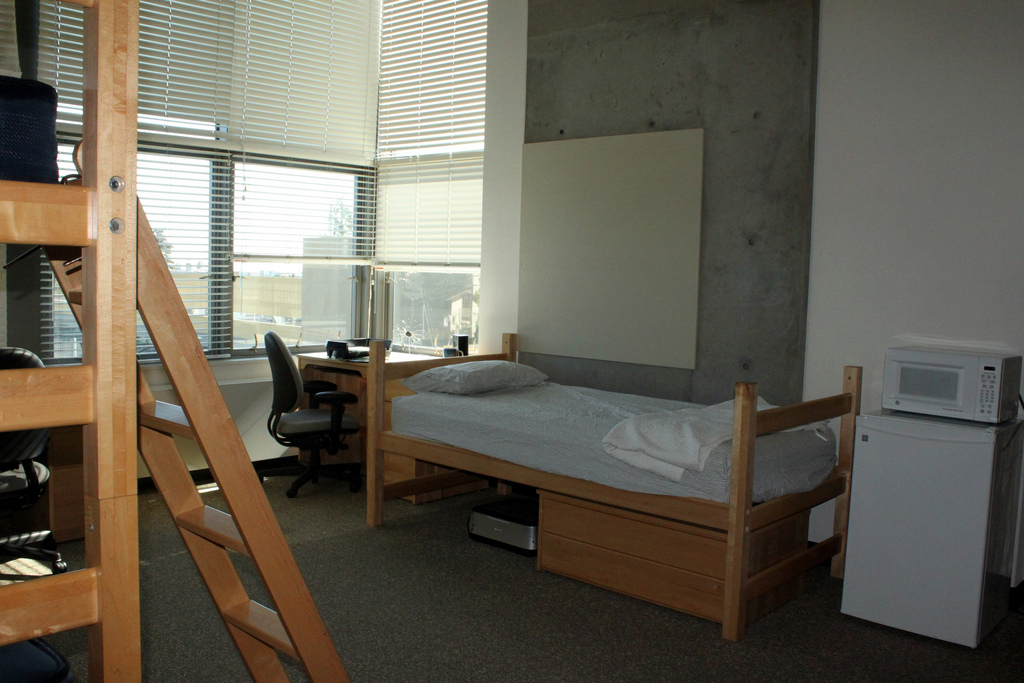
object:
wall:
[517, 0, 818, 407]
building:
[0, 0, 1024, 683]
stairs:
[49, 189, 345, 683]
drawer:
[536, 490, 815, 624]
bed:
[362, 333, 863, 644]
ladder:
[41, 189, 345, 683]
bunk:
[0, 0, 58, 183]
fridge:
[838, 348, 1018, 649]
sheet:
[600, 395, 832, 483]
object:
[468, 496, 539, 556]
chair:
[265, 331, 363, 499]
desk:
[298, 346, 493, 526]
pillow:
[402, 360, 550, 395]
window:
[228, 163, 370, 352]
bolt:
[109, 175, 125, 192]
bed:
[0, 0, 343, 683]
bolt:
[110, 218, 126, 235]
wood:
[0, 0, 347, 683]